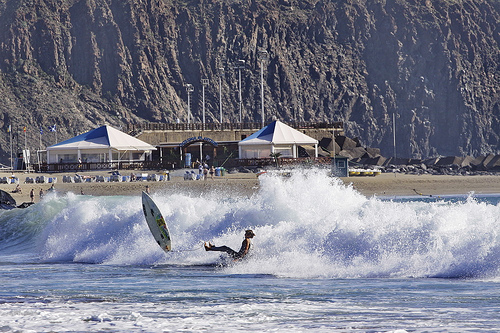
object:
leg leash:
[171, 244, 203, 252]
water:
[0, 195, 499, 333]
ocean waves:
[0, 290, 500, 332]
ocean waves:
[0, 167, 500, 279]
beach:
[0, 172, 500, 206]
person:
[204, 230, 255, 259]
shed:
[331, 157, 349, 177]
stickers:
[157, 218, 164, 226]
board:
[141, 192, 170, 254]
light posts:
[260, 62, 264, 129]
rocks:
[420, 163, 427, 170]